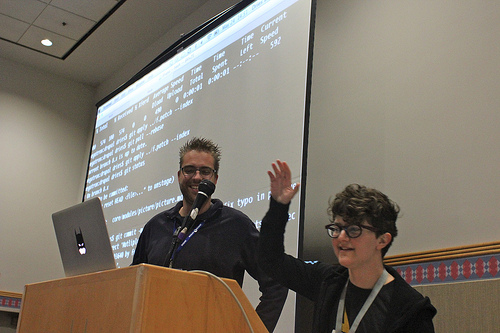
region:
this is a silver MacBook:
[21, 127, 132, 289]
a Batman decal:
[59, 220, 102, 262]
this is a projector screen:
[67, 6, 332, 313]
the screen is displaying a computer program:
[67, 7, 362, 329]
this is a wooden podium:
[2, 251, 280, 331]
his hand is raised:
[252, 117, 457, 331]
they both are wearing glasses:
[94, 90, 456, 332]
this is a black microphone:
[170, 152, 231, 231]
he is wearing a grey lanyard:
[317, 157, 404, 331]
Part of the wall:
[382, 82, 431, 133]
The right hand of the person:
[263, 157, 303, 207]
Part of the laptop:
[68, 213, 90, 220]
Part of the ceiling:
[97, 24, 137, 44]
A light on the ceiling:
[38, 37, 55, 50]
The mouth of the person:
[336, 242, 357, 254]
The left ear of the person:
[375, 229, 394, 250]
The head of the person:
[323, 181, 402, 272]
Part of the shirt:
[216, 243, 226, 264]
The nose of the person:
[334, 224, 351, 243]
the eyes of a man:
[171, 156, 227, 186]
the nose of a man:
[184, 167, 212, 192]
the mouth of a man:
[174, 161, 254, 209]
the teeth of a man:
[177, 171, 231, 208]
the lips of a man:
[176, 177, 224, 213]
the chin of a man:
[164, 174, 219, 221]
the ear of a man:
[170, 161, 191, 190]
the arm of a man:
[224, 211, 304, 329]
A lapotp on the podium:
[51, 199, 116, 279]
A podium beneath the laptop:
[16, 264, 267, 332]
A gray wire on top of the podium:
[188, 268, 252, 332]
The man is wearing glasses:
[178, 165, 213, 177]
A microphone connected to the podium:
[170, 179, 217, 264]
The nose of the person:
[338, 227, 349, 242]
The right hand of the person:
[268, 161, 300, 203]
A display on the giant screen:
[79, 0, 315, 332]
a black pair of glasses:
[316, 220, 382, 244]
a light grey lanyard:
[313, 259, 388, 324]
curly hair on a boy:
[320, 178, 406, 251]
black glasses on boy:
[317, 205, 405, 265]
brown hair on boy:
[335, 179, 409, 241]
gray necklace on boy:
[308, 262, 403, 332]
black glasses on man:
[174, 156, 225, 186]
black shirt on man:
[130, 201, 287, 263]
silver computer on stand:
[44, 198, 148, 272]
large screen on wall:
[72, 73, 319, 247]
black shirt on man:
[144, 188, 279, 286]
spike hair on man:
[168, 131, 232, 171]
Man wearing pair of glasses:
[132, 127, 291, 327]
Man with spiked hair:
[121, 131, 287, 316]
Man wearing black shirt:
[111, 136, 275, 329]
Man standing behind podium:
[115, 127, 287, 320]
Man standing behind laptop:
[123, 131, 285, 320]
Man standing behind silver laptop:
[129, 125, 290, 322]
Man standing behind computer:
[111, 135, 288, 328]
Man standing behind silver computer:
[130, 138, 290, 324]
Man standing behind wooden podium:
[129, 140, 297, 321]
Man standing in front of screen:
[102, 120, 307, 319]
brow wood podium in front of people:
[15, 258, 260, 330]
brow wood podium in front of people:
[9, 260, 275, 327]